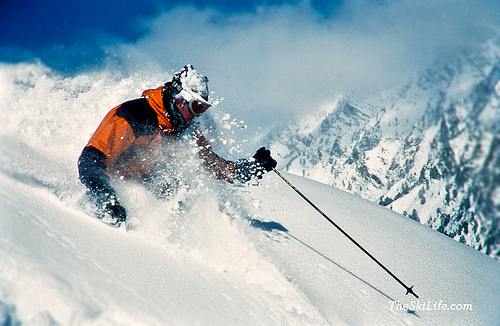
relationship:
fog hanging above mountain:
[60, 0, 498, 150] [252, 27, 499, 263]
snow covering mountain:
[7, 63, 498, 322] [1, 125, 484, 323]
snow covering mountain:
[240, 26, 483, 261] [230, 19, 485, 261]